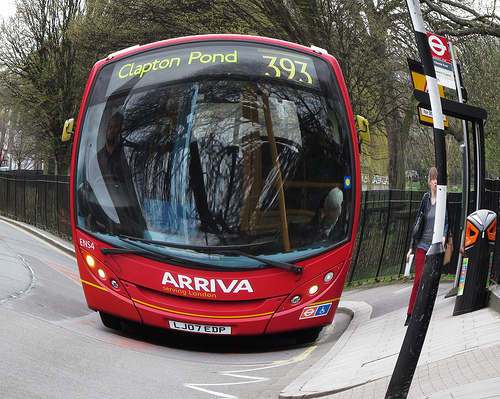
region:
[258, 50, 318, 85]
route number on bus display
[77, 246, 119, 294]
right side front head lights of bus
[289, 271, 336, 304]
left side front head lights on bus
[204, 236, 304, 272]
left windshield wiper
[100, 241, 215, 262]
right windshield wiper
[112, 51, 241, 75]
route name on bus display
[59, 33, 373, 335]
a red transportation bus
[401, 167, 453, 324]
woman on sidewalk at bus stop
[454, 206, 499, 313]
black and orange street trash can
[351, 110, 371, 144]
driver side mirror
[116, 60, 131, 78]
yellow letter on bus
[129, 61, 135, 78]
yellow letter on bus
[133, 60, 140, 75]
yellow letter on bus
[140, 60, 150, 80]
yellow letter on bus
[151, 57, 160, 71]
yellow letter on bus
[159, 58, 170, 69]
yellow letter on bus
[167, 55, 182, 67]
yellow letter on bus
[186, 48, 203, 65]
yellow letter on bus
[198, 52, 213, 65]
yellow letter on bus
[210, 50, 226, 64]
yellow letter on bus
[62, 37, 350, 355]
front of the bus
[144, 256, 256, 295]
brand of the bus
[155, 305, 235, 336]
license plate of bus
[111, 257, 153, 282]
the bus is red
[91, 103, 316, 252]
windshield of the bus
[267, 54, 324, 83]
number of the bus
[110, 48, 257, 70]
destination of the bus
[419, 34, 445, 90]
sign on the pole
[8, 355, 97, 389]
the ground is asphalt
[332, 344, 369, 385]
the sidewalk is concrete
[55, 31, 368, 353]
bus on the street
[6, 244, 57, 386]
road for vehicles to travel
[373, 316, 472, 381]
sidewalk for the pedestrians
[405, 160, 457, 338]
person walking on sidewalk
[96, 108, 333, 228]
window on the bus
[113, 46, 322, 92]
bus route and info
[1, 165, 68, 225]
gate alongside the sidewalk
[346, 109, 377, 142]
mirror on the bus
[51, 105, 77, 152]
mirror on the bus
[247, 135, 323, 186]
seats on the bus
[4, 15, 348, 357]
front of the bus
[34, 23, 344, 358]
front of the bus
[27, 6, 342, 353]
front of the bus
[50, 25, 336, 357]
front of the bus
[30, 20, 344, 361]
front of the bus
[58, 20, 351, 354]
front of the bus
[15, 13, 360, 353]
front of the bus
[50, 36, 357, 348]
front of the bus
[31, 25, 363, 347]
front of the bus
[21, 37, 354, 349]
front of the bus